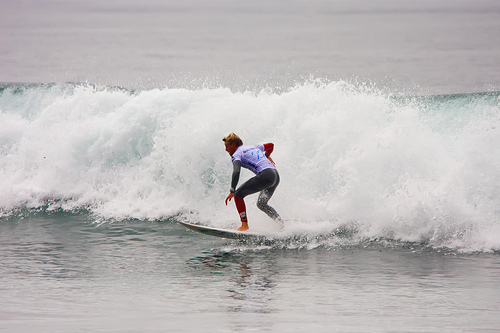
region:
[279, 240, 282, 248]
part of a board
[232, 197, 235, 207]
part of a knee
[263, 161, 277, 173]
part of a shirt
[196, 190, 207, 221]
edge of a board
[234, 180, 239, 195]
part of an elbow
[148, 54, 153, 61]
part of the sea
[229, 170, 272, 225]
the long leg of a person surfing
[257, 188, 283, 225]
the long leg of a person surfing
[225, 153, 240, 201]
the long arm of a person surfing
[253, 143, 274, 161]
the long arm of a person surfing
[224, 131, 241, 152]
the head of a person surfing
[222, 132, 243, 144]
the bright blond hair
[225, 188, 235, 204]
the hand of the surfer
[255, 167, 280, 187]
the bum of the surfer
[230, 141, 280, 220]
the black and red wetsuit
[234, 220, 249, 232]
the foot of the surfer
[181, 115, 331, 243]
the man is sufing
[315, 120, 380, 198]
the wave is coming in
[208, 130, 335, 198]
the mans shirt is purple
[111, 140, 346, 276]
the man is on a surfboard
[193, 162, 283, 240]
the mans pants are black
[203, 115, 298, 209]
the man has a number on his shirt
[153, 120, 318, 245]
the surfer is a man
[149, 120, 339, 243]
the man is in mid surf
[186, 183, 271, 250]
one side of the mans pants is red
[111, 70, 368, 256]
the man is surfing on the wave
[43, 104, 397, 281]
a man is surfing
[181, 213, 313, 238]
white color curf board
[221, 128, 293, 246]
a man standing in the surfboard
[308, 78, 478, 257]
big waves in the sea water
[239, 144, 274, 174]
a man wearing white color t-shirt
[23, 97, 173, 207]
white foam near the surfboard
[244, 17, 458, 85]
small waves in the sea water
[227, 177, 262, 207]
a person bending his knee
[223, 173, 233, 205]
hand of the person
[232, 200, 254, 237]
leg of the person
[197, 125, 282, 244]
male surfer in ocean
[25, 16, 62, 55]
white clouds in blue sky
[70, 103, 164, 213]
white foam in ocean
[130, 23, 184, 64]
white clouds in blue sky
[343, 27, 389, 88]
white clouds in blue sky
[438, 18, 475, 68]
white clouds in blue sky